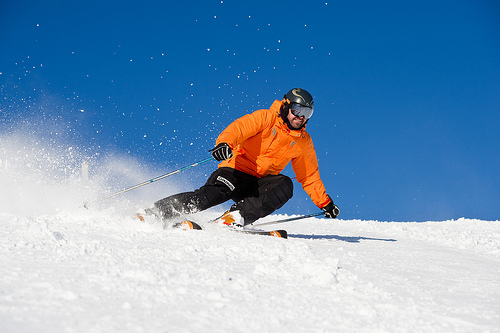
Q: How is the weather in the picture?
A: It is clear.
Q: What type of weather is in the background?
A: It is clear.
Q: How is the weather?
A: It is clear.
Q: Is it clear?
A: Yes, it is clear.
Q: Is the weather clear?
A: Yes, it is clear.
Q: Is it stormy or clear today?
A: It is clear.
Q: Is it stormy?
A: No, it is clear.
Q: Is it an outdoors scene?
A: Yes, it is outdoors.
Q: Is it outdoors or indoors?
A: It is outdoors.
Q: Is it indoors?
A: No, it is outdoors.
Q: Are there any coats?
A: Yes, there is a coat.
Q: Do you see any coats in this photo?
A: Yes, there is a coat.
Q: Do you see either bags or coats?
A: Yes, there is a coat.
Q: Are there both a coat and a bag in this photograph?
A: No, there is a coat but no bags.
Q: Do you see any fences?
A: No, there are no fences.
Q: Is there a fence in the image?
A: No, there are no fences.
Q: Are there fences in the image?
A: No, there are no fences.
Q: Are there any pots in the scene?
A: No, there are no pots.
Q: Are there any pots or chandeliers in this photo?
A: No, there are no pots or chandeliers.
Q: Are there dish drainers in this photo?
A: No, there are no dish drainers.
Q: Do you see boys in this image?
A: No, there are no boys.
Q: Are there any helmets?
A: Yes, there is a helmet.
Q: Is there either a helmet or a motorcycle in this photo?
A: Yes, there is a helmet.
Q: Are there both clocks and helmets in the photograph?
A: No, there is a helmet but no clocks.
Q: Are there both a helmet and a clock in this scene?
A: No, there is a helmet but no clocks.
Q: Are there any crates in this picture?
A: No, there are no crates.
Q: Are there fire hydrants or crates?
A: No, there are no crates or fire hydrants.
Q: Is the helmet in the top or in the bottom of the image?
A: The helmet is in the top of the image.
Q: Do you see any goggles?
A: Yes, there are goggles.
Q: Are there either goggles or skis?
A: Yes, there are goggles.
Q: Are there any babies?
A: No, there are no babies.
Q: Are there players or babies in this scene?
A: No, there are no babies or players.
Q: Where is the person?
A: The skier is in the snow.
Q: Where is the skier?
A: The skier is in the snow.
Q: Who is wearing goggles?
A: The skier is wearing goggles.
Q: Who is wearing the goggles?
A: The skier is wearing goggles.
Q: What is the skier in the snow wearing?
A: The skier is wearing goggles.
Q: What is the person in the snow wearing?
A: The skier is wearing goggles.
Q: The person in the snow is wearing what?
A: The skier is wearing goggles.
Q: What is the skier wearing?
A: The skier is wearing goggles.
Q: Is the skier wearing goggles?
A: Yes, the skier is wearing goggles.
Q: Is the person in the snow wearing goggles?
A: Yes, the skier is wearing goggles.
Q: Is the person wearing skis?
A: No, the skier is wearing goggles.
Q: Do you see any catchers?
A: No, there are no catchers.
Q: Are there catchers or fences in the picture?
A: No, there are no catchers or fences.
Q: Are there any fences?
A: No, there are no fences.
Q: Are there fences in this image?
A: No, there are no fences.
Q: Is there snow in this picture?
A: Yes, there is snow.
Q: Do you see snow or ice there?
A: Yes, there is snow.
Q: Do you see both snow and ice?
A: No, there is snow but no ice.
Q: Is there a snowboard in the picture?
A: No, there are no snowboards.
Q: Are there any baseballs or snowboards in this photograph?
A: No, there are no snowboards or baseballs.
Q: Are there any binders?
A: No, there are no binders.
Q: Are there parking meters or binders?
A: No, there are no binders or parking meters.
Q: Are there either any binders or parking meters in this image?
A: No, there are no binders or parking meters.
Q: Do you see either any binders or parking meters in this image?
A: No, there are no binders or parking meters.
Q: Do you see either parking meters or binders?
A: No, there are no binders or parking meters.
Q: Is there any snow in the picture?
A: Yes, there is snow.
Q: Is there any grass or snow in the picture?
A: Yes, there is snow.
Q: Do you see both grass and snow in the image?
A: No, there is snow but no grass.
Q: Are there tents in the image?
A: No, there are no tents.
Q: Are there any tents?
A: No, there are no tents.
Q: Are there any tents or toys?
A: No, there are no tents or toys.